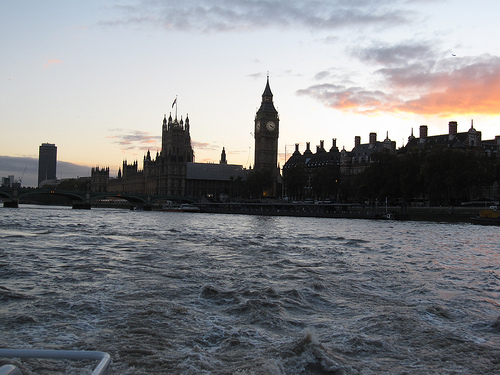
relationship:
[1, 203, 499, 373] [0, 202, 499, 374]
body of water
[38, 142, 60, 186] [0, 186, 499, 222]
building standing by shore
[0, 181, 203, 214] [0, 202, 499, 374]
bridge standing across water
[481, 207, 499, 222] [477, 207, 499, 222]
bowl inside of a bowl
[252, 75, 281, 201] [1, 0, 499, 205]
big ben standing on other side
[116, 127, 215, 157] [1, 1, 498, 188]
cloud floating in sky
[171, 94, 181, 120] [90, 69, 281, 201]
flag flying atop building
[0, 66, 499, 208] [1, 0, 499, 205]
town standing on other side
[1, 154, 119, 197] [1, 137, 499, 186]
mountain standing in distance